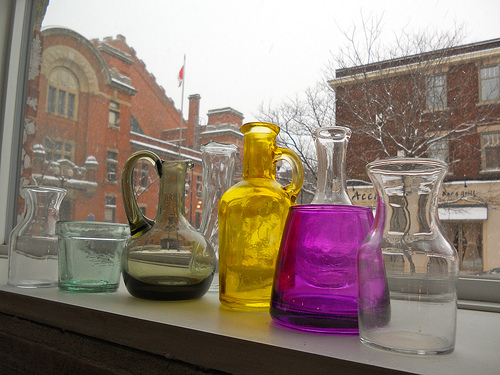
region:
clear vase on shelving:
[350, 155, 458, 363]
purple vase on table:
[262, 200, 393, 340]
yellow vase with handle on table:
[210, 115, 305, 320]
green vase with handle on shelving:
[106, 145, 211, 305]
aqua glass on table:
[50, 210, 132, 301]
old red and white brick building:
[25, 20, 241, 252]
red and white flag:
[170, 55, 191, 125]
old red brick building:
[312, 30, 493, 300]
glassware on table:
[0, 110, 495, 370]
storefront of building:
[335, 167, 495, 284]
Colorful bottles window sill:
[6, 102, 477, 357]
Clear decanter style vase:
[361, 158, 469, 368]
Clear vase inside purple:
[268, 117, 376, 329]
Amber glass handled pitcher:
[216, 119, 306, 306]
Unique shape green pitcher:
[119, 150, 217, 305]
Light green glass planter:
[52, 214, 135, 301]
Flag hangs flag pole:
[173, 49, 190, 144]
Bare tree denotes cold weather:
[336, 16, 485, 149]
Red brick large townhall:
[38, 28, 158, 150]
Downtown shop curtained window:
[443, 184, 498, 277]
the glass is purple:
[262, 185, 370, 343]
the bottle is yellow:
[188, 91, 309, 348]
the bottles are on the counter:
[12, 60, 430, 369]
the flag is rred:
[161, 50, 206, 97]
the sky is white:
[190, 10, 265, 65]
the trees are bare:
[261, 52, 474, 233]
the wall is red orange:
[88, 102, 140, 192]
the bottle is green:
[107, 132, 262, 323]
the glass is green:
[34, 206, 160, 294]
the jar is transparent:
[335, 125, 471, 368]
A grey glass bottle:
[115, 146, 221, 301]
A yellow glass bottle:
[218, 110, 301, 320]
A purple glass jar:
[263, 196, 390, 332]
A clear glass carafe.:
[356, 157, 483, 372]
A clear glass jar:
[47, 208, 131, 293]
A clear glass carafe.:
[1, 176, 73, 296]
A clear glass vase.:
[188, 131, 235, 258]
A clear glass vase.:
[308, 119, 354, 212]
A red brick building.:
[30, 14, 245, 161]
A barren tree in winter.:
[263, 10, 490, 137]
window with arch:
[46, 65, 82, 119]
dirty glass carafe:
[358, 153, 460, 351]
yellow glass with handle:
[216, 120, 303, 308]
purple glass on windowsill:
[266, 204, 389, 334]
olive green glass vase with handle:
[117, 148, 217, 302]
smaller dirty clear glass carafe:
[6, 185, 64, 287]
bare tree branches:
[310, 3, 493, 175]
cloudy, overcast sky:
[45, 5, 498, 120]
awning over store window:
[434, 200, 490, 225]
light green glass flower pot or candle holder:
[56, 220, 126, 291]